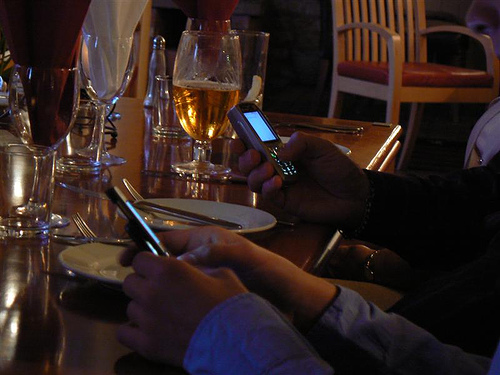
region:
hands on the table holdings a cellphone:
[103, 181, 497, 371]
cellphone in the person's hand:
[225, 100, 379, 222]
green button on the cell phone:
[269, 152, 279, 159]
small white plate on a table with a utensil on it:
[122, 193, 280, 233]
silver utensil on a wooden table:
[269, 112, 364, 137]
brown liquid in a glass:
[166, 25, 243, 177]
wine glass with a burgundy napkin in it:
[2, 1, 90, 230]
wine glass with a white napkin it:
[77, 0, 150, 166]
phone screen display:
[243, 109, 280, 142]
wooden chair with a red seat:
[332, 0, 499, 125]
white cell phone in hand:
[233, 101, 297, 180]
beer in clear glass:
[173, 31, 240, 179]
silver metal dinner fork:
[124, 181, 239, 233]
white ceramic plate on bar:
[121, 195, 277, 240]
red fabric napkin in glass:
[4, 0, 83, 133]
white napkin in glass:
[84, 5, 142, 99]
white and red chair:
[328, 3, 498, 121]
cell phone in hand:
[108, 177, 183, 271]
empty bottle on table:
[148, 37, 168, 110]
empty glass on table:
[240, 28, 268, 115]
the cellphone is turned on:
[223, 92, 304, 190]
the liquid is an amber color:
[168, 70, 242, 136]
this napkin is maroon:
[9, 0, 80, 145]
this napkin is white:
[81, 2, 163, 85]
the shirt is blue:
[181, 299, 305, 368]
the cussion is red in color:
[348, 60, 484, 87]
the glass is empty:
[0, 134, 56, 254]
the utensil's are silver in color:
[58, 167, 233, 242]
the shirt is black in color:
[358, 156, 490, 242]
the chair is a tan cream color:
[322, 4, 499, 125]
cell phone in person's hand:
[232, 102, 309, 194]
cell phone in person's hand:
[86, 173, 178, 268]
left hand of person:
[101, 252, 271, 363]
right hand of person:
[183, 207, 323, 308]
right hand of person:
[248, 141, 362, 205]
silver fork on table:
[71, 211, 104, 243]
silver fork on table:
[119, 177, 154, 197]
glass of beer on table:
[166, 31, 241, 183]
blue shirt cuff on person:
[168, 292, 302, 364]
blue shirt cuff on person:
[303, 282, 415, 364]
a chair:
[351, 14, 475, 94]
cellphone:
[223, 104, 305, 186]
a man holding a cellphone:
[98, 186, 185, 262]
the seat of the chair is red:
[407, 53, 447, 86]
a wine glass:
[13, 63, 70, 155]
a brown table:
[351, 134, 381, 159]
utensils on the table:
[306, 114, 364, 141]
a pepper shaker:
[149, 43, 168, 75]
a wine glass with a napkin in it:
[82, 33, 147, 103]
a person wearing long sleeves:
[218, 323, 288, 373]